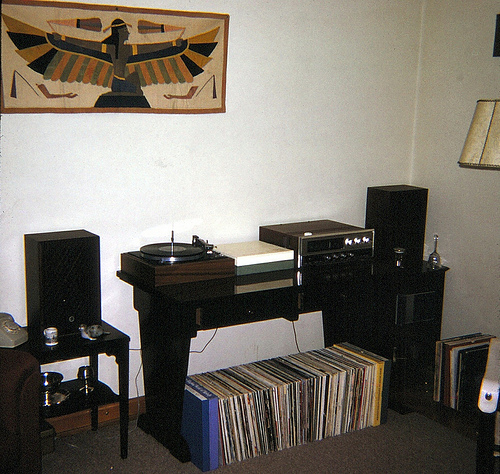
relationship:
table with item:
[8, 308, 144, 471] [73, 313, 115, 345]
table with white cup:
[8, 308, 144, 471] [42, 323, 59, 345]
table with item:
[8, 308, 144, 471] [13, 218, 115, 339]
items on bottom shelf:
[48, 364, 113, 414] [42, 375, 117, 417]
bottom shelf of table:
[42, 375, 117, 417] [18, 320, 130, 459]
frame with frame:
[0, 0, 230, 117] [0, 0, 230, 117]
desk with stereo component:
[116, 249, 449, 464] [258, 218, 374, 269]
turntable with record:
[118, 227, 236, 289] [139, 240, 204, 260]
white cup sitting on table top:
[42, 323, 59, 345] [18, 320, 131, 359]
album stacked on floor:
[180, 383, 208, 471] [40, 408, 477, 472]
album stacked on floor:
[187, 375, 220, 470] [40, 408, 477, 472]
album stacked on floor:
[332, 344, 384, 426] [40, 408, 477, 472]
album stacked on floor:
[340, 341, 391, 425] [40, 408, 477, 472]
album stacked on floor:
[299, 352, 346, 435] [40, 408, 477, 472]